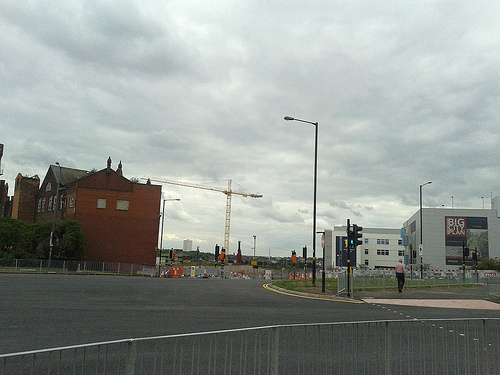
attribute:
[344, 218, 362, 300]
traffic signal — black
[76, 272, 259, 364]
street — dotted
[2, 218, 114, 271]
bushes — high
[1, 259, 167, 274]
fence — metal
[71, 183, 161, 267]
wall — red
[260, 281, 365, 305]
line — yellow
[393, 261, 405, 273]
shirt — pink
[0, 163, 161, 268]
building — old, brick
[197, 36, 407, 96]
clouds — grey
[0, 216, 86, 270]
trees — green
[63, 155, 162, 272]
building — red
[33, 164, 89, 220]
building — red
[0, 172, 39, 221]
building — red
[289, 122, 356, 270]
light pole — tall, black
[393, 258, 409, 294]
man — white haired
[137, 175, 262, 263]
crane — tall, yellow, large, orange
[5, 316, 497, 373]
fence — grey, metal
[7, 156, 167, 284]
building — reddish brown, apartment building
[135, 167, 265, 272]
crane — yellow 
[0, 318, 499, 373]
railing — silver, metal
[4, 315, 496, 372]
metal gate — metal 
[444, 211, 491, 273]
sign — big 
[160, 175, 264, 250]
equipment — tall, t shaped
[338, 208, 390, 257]
light — green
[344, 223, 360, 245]
lights — green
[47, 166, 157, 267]
red building — tall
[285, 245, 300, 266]
sign — construction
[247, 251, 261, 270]
sign — construction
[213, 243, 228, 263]
sign — construction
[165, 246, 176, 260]
sign — construction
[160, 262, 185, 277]
sign — construction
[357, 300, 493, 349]
line — dotted, white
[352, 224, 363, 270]
traffic signals — two traffic 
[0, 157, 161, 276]
building — red brick, side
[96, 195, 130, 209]
squares —  two white 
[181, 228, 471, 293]
site — construction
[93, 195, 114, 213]
blinds — white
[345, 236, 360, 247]
light — green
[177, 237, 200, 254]
building — tall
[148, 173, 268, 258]
construction crane — large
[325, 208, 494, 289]
buildings — white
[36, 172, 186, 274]
building — red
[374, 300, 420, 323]
lines — white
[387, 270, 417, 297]
chinos — black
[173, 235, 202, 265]
skyscraper — tall